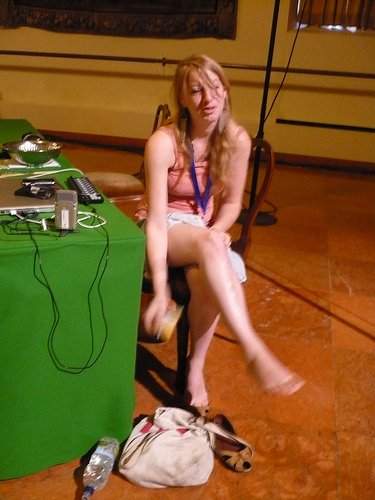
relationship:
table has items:
[1, 118, 145, 480] [1, 128, 119, 375]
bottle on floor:
[73, 430, 122, 499] [0, 143, 375, 498]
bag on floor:
[117, 408, 253, 488] [0, 143, 375, 498]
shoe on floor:
[209, 412, 254, 476] [0, 143, 375, 498]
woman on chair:
[135, 52, 306, 407] [129, 128, 283, 413]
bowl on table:
[0, 133, 65, 164] [1, 118, 145, 480]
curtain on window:
[297, 1, 374, 35] [286, 0, 374, 51]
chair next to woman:
[129, 128, 283, 413] [135, 52, 306, 407]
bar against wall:
[0, 49, 375, 81] [2, 0, 373, 158]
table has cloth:
[1, 118, 145, 480] [2, 116, 141, 491]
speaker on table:
[53, 190, 81, 234] [1, 118, 145, 480]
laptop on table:
[0, 173, 77, 215] [1, 118, 145, 480]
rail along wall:
[0, 46, 374, 80] [2, 0, 373, 158]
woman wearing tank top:
[135, 52, 306, 407] [136, 124, 243, 220]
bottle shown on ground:
[82, 434, 120, 493] [0, 145, 374, 498]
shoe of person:
[209, 412, 254, 476] [147, 63, 328, 409]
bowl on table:
[0, 133, 65, 164] [3, 170, 149, 427]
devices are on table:
[1, 176, 103, 236] [0, 212, 144, 296]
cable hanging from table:
[18, 202, 109, 373] [1, 118, 145, 480]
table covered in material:
[1, 118, 145, 480] [0, 117, 146, 477]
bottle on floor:
[82, 434, 120, 493] [0, 143, 375, 498]